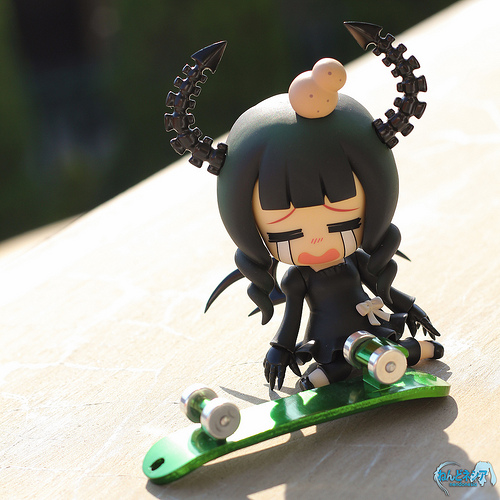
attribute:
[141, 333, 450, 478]
skateboard — green, upside down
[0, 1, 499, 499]
table — tan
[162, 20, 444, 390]
figure — sitting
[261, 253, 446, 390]
clothing — black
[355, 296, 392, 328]
bow — white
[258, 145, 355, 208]
bang — black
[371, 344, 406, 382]
wheel — silver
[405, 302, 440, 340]
hand — black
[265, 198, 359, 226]
eyebrows — red